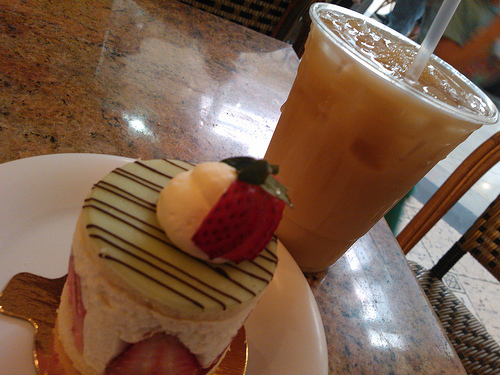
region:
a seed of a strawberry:
[208, 222, 221, 238]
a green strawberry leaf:
[255, 170, 296, 211]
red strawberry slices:
[191, 178, 288, 266]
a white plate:
[1, 148, 336, 372]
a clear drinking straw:
[401, 0, 463, 87]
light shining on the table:
[193, 93, 282, 158]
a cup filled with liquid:
[252, 2, 499, 274]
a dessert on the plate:
[45, 144, 302, 374]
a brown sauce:
[4, 261, 62, 373]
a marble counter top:
[1, 0, 468, 372]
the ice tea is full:
[263, 12, 467, 192]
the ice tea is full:
[305, 20, 437, 140]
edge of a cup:
[377, 62, 407, 92]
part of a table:
[378, 309, 408, 351]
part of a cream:
[188, 214, 221, 271]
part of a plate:
[283, 308, 306, 343]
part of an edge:
[160, 299, 198, 337]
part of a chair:
[441, 276, 461, 307]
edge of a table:
[414, 273, 431, 330]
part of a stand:
[434, 251, 453, 282]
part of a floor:
[432, 229, 448, 251]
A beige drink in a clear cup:
[251, 5, 489, 286]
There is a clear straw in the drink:
[316, 18, 486, 141]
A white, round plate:
[3, 134, 341, 364]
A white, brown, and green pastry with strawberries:
[47, 140, 293, 372]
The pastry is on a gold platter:
[6, 197, 278, 370]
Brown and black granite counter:
[17, 5, 453, 374]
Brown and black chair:
[375, 145, 492, 365]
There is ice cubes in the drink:
[314, 9, 484, 181]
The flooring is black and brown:
[379, 118, 491, 359]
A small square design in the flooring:
[433, 251, 471, 306]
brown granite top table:
[69, 53, 204, 135]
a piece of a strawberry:
[207, 148, 291, 263]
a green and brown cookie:
[77, 171, 270, 331]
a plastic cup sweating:
[296, 51, 425, 283]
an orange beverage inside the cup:
[322, 1, 400, 231]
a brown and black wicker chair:
[438, 208, 498, 307]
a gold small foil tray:
[17, 263, 52, 343]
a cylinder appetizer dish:
[61, 263, 277, 362]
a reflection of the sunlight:
[113, 16, 265, 125]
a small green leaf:
[239, 142, 296, 208]